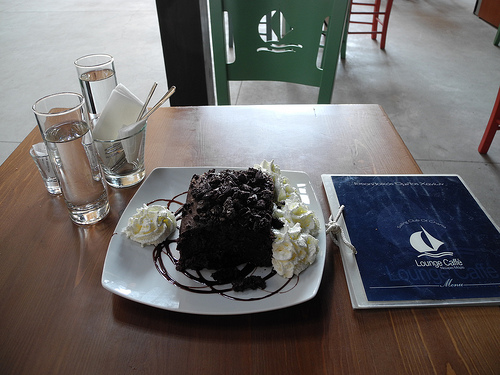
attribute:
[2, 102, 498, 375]
table — wooden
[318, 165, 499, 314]
menu — blue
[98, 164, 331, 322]
plate — white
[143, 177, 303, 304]
sauce — chocolate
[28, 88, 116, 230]
glass — clear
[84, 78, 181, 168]
napkin — white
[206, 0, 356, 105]
chair — green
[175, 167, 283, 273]
cake — chocolate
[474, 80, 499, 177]
leg — red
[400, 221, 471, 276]
logo — boat, white, sailboat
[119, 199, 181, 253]
cream — whipped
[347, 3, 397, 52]
chair — red